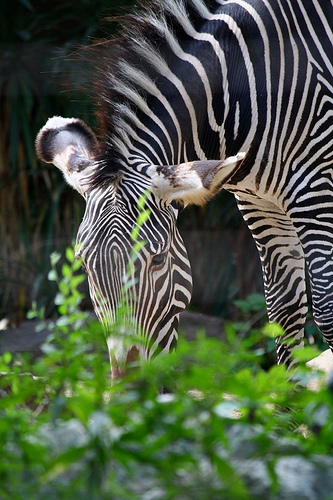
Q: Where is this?
A: This is at the field.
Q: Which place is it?
A: It is a field.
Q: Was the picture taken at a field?
A: Yes, it was taken in a field.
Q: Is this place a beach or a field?
A: It is a field.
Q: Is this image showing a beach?
A: No, the picture is showing a field.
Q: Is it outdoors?
A: Yes, it is outdoors.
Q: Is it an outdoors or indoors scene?
A: It is outdoors.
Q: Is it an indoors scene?
A: No, it is outdoors.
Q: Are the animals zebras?
A: Yes, all the animals are zebras.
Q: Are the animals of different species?
A: No, all the animals are zebras.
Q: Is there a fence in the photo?
A: No, there are no fences.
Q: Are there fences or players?
A: No, there are no fences or players.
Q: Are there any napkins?
A: No, there are no napkins.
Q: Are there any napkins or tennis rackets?
A: No, there are no napkins or tennis rackets.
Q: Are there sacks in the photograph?
A: No, there are no sacks.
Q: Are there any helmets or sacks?
A: No, there are no sacks or helmets.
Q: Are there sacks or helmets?
A: No, there are no sacks or helmets.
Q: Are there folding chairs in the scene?
A: No, there are no folding chairs.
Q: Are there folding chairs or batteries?
A: No, there are no folding chairs or batteries.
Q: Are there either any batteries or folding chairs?
A: No, there are no folding chairs or batteries.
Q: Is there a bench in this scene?
A: No, there are no benches.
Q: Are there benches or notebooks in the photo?
A: No, there are no benches or notebooks.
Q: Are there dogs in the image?
A: No, there are no dogs.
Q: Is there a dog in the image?
A: No, there are no dogs.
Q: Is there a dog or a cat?
A: No, there are no dogs or cats.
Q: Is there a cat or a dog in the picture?
A: No, there are no dogs or cats.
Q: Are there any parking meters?
A: No, there are no parking meters.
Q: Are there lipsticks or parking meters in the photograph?
A: No, there are no parking meters or lipsticks.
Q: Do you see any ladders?
A: No, there are no ladders.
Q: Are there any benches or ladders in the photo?
A: No, there are no ladders or benches.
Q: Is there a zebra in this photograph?
A: Yes, there is a zebra.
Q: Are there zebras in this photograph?
A: Yes, there is a zebra.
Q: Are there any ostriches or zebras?
A: Yes, there is a zebra.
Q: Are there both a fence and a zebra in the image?
A: No, there is a zebra but no fences.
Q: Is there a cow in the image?
A: No, there are no cows.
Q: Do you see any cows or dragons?
A: No, there are no cows or dragons.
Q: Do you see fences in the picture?
A: No, there are no fences.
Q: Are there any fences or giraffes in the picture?
A: No, there are no fences or giraffes.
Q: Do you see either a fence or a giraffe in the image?
A: No, there are no fences or giraffes.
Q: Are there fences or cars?
A: No, there are no fences or cars.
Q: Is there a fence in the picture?
A: No, there are no fences.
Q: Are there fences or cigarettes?
A: No, there are no fences or cigarettes.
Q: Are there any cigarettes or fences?
A: No, there are no fences or cigarettes.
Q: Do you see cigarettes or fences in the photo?
A: No, there are no fences or cigarettes.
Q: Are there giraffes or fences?
A: No, there are no fences or giraffes.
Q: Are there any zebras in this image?
A: Yes, there is a zebra.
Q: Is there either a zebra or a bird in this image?
A: Yes, there is a zebra.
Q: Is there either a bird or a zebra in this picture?
A: Yes, there is a zebra.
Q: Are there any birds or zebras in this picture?
A: Yes, there is a zebra.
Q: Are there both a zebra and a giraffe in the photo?
A: No, there is a zebra but no giraffes.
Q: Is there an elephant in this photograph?
A: No, there are no elephants.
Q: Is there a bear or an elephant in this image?
A: No, there are no elephants or bears.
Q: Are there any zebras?
A: Yes, there is a zebra.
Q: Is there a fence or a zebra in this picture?
A: Yes, there is a zebra.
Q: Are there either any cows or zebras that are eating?
A: Yes, the zebra is eating.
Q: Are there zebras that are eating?
A: Yes, there is a zebra that is eating.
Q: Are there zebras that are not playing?
A: Yes, there is a zebra that is eating.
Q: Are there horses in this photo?
A: No, there are no horses.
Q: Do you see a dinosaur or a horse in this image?
A: No, there are no horses or dinosaurs.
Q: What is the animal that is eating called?
A: The animal is a zebra.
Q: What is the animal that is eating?
A: The animal is a zebra.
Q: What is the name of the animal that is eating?
A: The animal is a zebra.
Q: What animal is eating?
A: The animal is a zebra.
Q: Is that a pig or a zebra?
A: That is a zebra.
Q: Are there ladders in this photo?
A: No, there are no ladders.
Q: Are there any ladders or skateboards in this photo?
A: No, there are no ladders or skateboards.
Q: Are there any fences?
A: No, there are no fences.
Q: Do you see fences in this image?
A: No, there are no fences.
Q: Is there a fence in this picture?
A: No, there are no fences.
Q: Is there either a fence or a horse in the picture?
A: No, there are no fences or horses.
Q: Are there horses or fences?
A: No, there are no fences or horses.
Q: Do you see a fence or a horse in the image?
A: No, there are no fences or horses.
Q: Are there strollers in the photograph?
A: No, there are no strollers.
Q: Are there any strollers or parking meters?
A: No, there are no strollers or parking meters.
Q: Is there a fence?
A: No, there are no fences.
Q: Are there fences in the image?
A: No, there are no fences.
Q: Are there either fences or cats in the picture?
A: No, there are no fences or cats.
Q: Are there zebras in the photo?
A: Yes, there is a zebra.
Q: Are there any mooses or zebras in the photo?
A: Yes, there is a zebra.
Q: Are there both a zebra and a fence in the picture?
A: No, there is a zebra but no fences.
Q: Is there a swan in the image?
A: No, there are no swans.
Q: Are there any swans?
A: No, there are no swans.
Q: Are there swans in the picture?
A: No, there are no swans.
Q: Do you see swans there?
A: No, there are no swans.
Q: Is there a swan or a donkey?
A: No, there are no swans or donkeys.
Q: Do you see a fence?
A: No, there are no fences.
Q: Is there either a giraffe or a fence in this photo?
A: No, there are no fences or giraffes.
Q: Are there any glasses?
A: No, there are no glasses.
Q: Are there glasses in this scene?
A: No, there are no glasses.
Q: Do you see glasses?
A: No, there are no glasses.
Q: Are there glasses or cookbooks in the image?
A: No, there are no glasses or cookbooks.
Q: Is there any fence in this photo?
A: No, there are no fences.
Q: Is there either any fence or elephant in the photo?
A: No, there are no fences or elephants.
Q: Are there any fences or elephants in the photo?
A: No, there are no fences or elephants.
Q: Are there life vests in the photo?
A: No, there are no life vests.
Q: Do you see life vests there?
A: No, there are no life vests.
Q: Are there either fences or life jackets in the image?
A: No, there are no life jackets or fences.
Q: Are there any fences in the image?
A: No, there are no fences.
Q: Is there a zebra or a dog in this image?
A: Yes, there is a zebra.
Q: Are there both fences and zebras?
A: No, there is a zebra but no fences.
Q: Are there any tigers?
A: No, there are no tigers.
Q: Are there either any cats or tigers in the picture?
A: No, there are no tigers or cats.